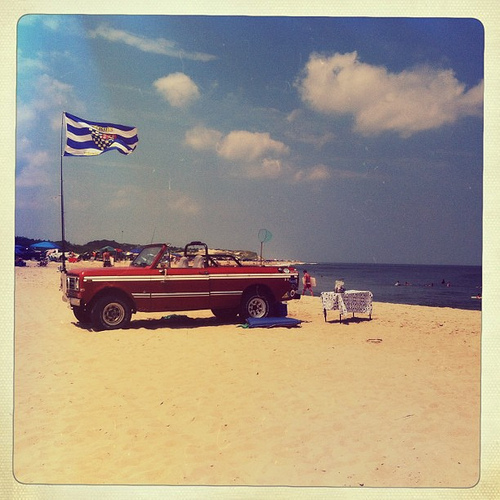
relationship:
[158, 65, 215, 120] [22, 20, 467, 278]
clouds in sky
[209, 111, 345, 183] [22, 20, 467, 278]
clouds in sky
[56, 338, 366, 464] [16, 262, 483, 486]
footprints in sand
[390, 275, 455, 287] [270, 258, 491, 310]
people in water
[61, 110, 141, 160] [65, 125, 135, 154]
flag with stripe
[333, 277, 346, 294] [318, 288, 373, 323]
bag on table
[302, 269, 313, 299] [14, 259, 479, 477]
people swimming in beach